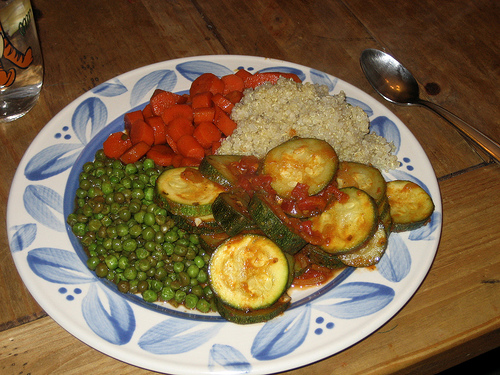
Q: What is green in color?
A: Peas.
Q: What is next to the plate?
A: Spoon.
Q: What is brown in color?
A: Table.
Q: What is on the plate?
A: Food.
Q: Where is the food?
A: On the plate.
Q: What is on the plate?
A: Vegetables.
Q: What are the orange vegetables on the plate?
A: Carrots.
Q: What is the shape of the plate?
A: Round.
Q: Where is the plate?
A: On a table.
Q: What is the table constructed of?
A: Wood.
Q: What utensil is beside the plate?
A: Spoon.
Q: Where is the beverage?
A: Behind the plate.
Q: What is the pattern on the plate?
A: Floral.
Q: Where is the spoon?
A: Beside the plate.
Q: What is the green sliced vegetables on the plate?
A: Zucchini.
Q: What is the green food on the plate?
A: Squash and peas.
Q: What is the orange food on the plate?
A: Carrots.